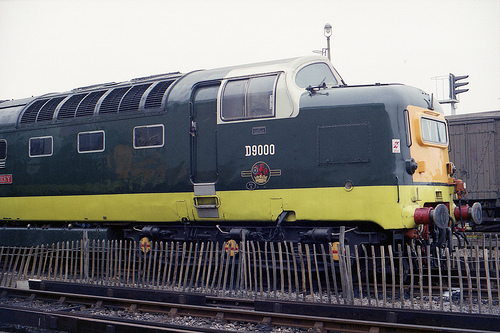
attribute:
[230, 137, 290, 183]
logo — red, gold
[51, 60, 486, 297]
train — yellow, green, striped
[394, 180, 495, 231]
bumper — black, red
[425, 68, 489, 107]
cage — steel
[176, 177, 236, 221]
step — grey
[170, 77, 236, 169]
door — green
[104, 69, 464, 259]
train — white, numbered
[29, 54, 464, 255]
train — black, yellow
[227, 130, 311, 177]
numbers — white, painted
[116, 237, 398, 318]
fence — wood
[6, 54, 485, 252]
car — train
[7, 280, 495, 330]
track — train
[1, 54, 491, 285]
train — green, yellow, black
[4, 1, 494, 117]
sky — cloudy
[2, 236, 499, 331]
tracks — train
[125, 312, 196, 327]
rocks — small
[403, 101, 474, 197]
front — yellow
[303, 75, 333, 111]
wiper — windshield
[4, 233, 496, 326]
fence — old, broken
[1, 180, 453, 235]
stripe — yellow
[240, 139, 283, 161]
numbers — white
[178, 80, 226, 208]
door — green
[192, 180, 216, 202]
step — silver